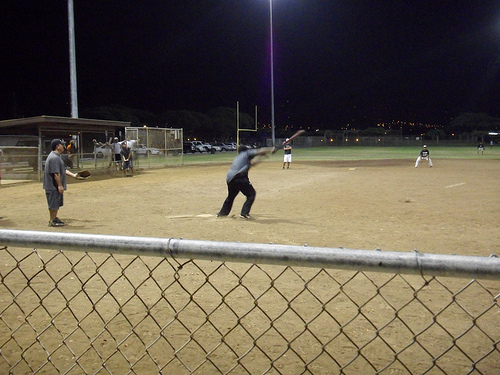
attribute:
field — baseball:
[165, 144, 489, 258]